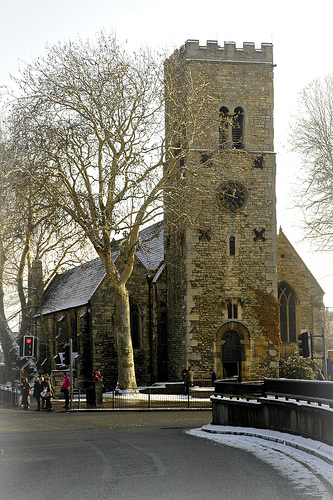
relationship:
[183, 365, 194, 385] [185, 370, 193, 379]
person wearing brown coat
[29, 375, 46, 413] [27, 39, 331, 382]
person in front of church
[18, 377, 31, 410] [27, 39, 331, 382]
person in front of church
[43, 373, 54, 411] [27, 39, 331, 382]
person in front of church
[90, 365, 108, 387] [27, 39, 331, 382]
person in front of church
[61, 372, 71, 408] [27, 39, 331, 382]
person in front of church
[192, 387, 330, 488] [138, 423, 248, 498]
snow on ground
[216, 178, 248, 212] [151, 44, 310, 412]
clock on church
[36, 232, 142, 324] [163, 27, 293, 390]
roof of church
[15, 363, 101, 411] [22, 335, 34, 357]
pedestrians standing next to light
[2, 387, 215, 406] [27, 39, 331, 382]
fence surrounding church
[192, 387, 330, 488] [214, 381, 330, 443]
snow next to fence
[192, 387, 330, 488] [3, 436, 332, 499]
snow on ground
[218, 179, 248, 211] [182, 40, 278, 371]
clock on wall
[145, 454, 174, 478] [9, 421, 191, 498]
part of a road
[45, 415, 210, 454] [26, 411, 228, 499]
edge of a road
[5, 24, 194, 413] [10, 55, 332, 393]
tree near building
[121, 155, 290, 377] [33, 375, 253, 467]
building on street corner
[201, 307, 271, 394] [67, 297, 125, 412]
door of church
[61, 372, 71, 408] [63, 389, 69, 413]
person wearing pants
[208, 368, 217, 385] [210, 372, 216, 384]
person wearing coat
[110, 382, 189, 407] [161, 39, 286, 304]
fence in front of building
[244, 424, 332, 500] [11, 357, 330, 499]
tire tracks in wet street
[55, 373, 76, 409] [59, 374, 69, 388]
person wearing coat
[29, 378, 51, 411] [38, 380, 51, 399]
person wearing bag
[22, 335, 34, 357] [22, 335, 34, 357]
light are on light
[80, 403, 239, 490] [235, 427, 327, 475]
track in snow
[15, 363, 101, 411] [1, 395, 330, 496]
pedestrians are waiting to street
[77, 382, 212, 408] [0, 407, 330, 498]
fence lining street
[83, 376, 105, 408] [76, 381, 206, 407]
trash container behind fence